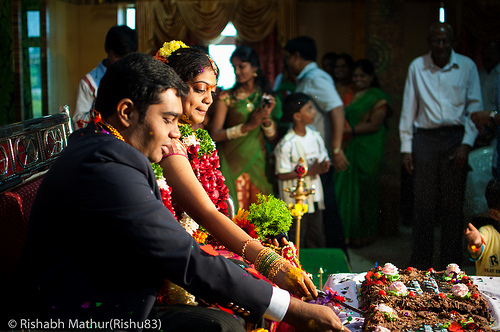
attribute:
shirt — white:
[397, 47, 482, 153]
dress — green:
[226, 90, 285, 205]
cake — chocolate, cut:
[361, 261, 499, 332]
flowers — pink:
[446, 259, 469, 298]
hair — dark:
[166, 49, 221, 81]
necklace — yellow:
[98, 118, 130, 143]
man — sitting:
[1, 55, 292, 313]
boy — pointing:
[462, 177, 499, 279]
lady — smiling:
[331, 61, 392, 246]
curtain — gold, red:
[135, 1, 300, 90]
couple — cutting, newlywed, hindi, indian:
[19, 40, 336, 313]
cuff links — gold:
[226, 303, 255, 320]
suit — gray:
[22, 128, 274, 332]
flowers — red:
[195, 148, 229, 214]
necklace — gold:
[239, 88, 261, 113]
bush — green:
[250, 195, 294, 240]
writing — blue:
[411, 278, 442, 297]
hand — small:
[463, 221, 488, 250]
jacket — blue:
[73, 58, 105, 133]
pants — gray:
[412, 126, 466, 273]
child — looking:
[274, 92, 331, 248]